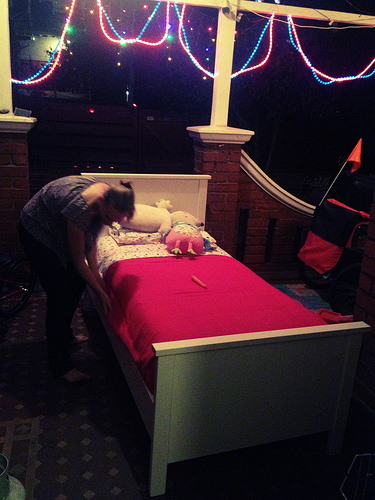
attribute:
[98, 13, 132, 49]
light — pink, blue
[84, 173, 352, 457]
bed — child's, small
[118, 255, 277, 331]
comforter — red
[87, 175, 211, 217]
headboard — white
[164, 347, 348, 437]
footboard — white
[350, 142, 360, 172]
flag — orange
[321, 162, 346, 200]
pole — white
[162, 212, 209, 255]
toy — stuffed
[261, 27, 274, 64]
light — blue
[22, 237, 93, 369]
pants — black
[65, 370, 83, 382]
foot — bare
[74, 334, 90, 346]
foot — bare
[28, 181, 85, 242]
shirt — blue, plaid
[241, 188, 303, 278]
wall — sloped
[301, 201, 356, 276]
blanket — red